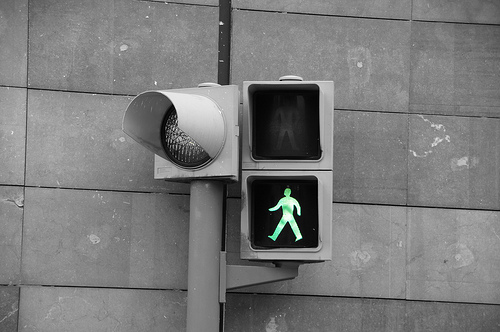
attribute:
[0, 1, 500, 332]
wall — old, gray, brick, rectangular, cinder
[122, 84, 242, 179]
light — off, gray, green, round, lighted, circular, close-up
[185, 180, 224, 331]
pole — gray, black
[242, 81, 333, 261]
signal — crosswalk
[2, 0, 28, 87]
block — cement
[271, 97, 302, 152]
man — green, walking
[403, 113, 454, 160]
stain — white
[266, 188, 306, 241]
person — walking, green, standing, still, lighted, square